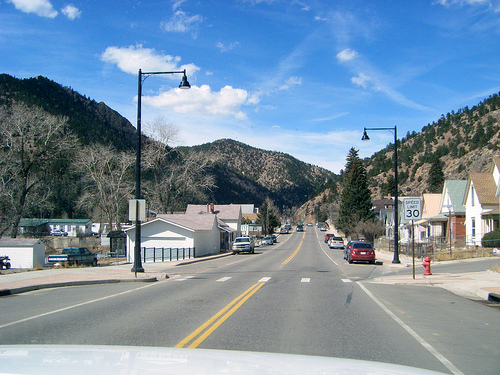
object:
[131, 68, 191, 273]
street light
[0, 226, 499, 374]
road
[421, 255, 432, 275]
fire hydrant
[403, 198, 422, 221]
sign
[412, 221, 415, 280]
pole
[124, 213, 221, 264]
house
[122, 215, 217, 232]
roof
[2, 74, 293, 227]
mountain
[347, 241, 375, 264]
car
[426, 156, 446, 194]
tree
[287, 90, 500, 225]
mountainside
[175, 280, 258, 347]
line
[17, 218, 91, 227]
roof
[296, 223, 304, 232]
vehicle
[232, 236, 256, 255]
vehicle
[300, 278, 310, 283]
line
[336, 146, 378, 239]
tree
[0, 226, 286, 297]
sidewalk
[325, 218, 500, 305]
sidewalk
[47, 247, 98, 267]
pickup truck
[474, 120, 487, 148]
tree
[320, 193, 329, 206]
tree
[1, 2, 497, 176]
sky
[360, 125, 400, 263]
street light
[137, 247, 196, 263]
fence